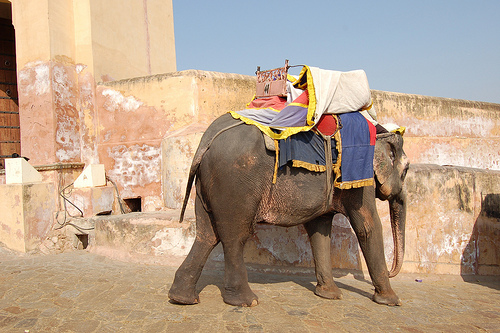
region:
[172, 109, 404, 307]
an adult elephant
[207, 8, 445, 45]
the blue sky in the background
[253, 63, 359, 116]
a seat on the elephant back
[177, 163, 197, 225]
the tail of the elephant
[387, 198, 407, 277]
the long elephant's trunk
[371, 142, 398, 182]
the ear of the elephant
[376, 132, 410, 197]
the head of the elephant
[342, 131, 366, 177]
a blue cloth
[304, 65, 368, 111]
this cloth is yellow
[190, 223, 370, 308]
the shadow of the elephant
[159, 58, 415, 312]
elephant with blankets on its back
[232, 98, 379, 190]
blankets on elephant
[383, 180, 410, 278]
trunk of elephant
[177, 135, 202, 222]
tail of large elephant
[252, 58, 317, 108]
seat on top of elephant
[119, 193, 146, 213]
opening in brick wall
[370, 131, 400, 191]
ear on head of elephant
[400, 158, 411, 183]
eye of large elephant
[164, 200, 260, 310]
back legs of elephant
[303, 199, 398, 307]
front legs of elephant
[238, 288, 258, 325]
There is an elephant's hoof here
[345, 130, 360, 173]
There is a blue and red blanket here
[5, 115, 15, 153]
There is brick that is back on this building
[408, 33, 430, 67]
There is a light blue sky pictured here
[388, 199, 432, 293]
This elephant has a long trunk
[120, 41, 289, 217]
This photo looks quite lovely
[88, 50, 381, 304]
This photo really has a sharp definition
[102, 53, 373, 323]
This photo was taken in the late afternoon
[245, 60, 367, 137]
howdah on elephant's back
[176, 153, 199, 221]
tail of elephant hanging down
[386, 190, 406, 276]
trunk on elephant's face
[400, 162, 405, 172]
eyeball of elephant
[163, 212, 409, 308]
four legs on elephant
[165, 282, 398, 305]
feet on elephant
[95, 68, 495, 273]
city wall made of stone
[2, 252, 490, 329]
city street made of stone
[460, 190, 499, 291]
shadow being cast onto ground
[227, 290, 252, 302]
The foot of an elephant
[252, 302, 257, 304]
The toe of an elephant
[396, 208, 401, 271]
The trunk of an elephant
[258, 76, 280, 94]
A seat on the elephant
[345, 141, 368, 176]
Blue cloth hanging on the side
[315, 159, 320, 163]
A hole in a blue cloth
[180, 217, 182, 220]
The tip of the tail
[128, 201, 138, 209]
A hole in the wall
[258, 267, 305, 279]
Shadow cast by elephant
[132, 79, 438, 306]
elephant on the dirt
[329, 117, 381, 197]
fabric on a elephant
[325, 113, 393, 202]
gold trim on fabric